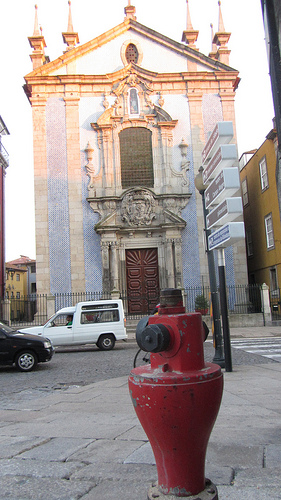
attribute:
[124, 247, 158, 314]
door — large, dark brown